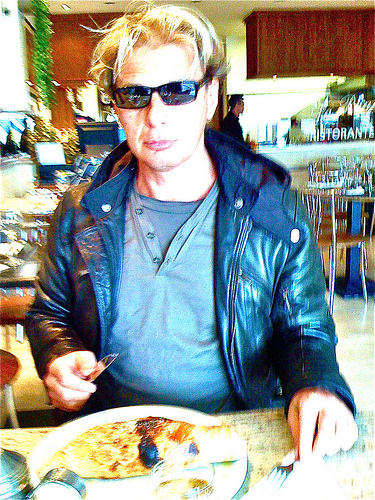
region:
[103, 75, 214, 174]
A man is wearing sunglasses.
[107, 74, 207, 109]
The color of a pair of sunglasses is black.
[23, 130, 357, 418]
A man is wearing a dark jacket.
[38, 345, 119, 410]
A man is holding a knife in his hand.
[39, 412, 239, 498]
Food is sitting on a plate.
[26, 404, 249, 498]
A plate is sitting on a table.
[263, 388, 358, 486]
A man is holding a fork in one hand.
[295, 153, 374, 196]
Glasses are sitting on a table.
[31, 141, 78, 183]
A laptop is sitting on a table.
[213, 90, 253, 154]
A man is in the background.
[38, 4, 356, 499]
man sitting at a table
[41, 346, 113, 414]
fingers wrapped around a knife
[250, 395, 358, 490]
fingers on a fork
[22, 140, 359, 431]
black leather jacket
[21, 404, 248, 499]
food on a white plate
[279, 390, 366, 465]
hand resting on a table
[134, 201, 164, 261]
row of three buttons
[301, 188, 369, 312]
brown and silver chair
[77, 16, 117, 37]
tuft of blonde hair sticking up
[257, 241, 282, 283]
wrinkles on the jacket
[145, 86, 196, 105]
man is wearing sunglasses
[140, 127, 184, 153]
man is wearing lipstick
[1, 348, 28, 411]
stool is behind the man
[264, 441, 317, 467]
man is holding a fork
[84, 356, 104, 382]
man is holding a knife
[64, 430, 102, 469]
man has an omelet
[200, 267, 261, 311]
man is wearing a leather jacket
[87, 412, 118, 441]
omelet is on the plate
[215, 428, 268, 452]
plate is on the table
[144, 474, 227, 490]
glass next to the plate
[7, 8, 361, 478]
the man is eating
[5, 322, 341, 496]
the man is holding a knife and fork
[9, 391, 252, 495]
food is on the plate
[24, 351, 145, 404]
the knife is silver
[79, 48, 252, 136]
the man is wearing sunglasses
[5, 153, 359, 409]
the man is wearing a jacket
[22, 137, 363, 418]
the jacket is black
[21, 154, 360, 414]
the jacket is leather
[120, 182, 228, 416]
the man is wearing a grey shirt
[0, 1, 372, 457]
the man is in a restaurant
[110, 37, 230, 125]
a man wearing sunglasses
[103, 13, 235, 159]
a man with blonde hair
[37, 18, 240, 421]
a man holding a knife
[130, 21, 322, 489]
a man holding a fork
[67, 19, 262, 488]
a man sitting at a table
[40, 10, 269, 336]
a man wearing a black leather jacket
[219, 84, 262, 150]
a man at a counter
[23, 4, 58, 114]
a green vine hanging down from cieling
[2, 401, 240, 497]
a pizza on a plate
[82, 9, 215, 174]
a man wearing dark sunglasses